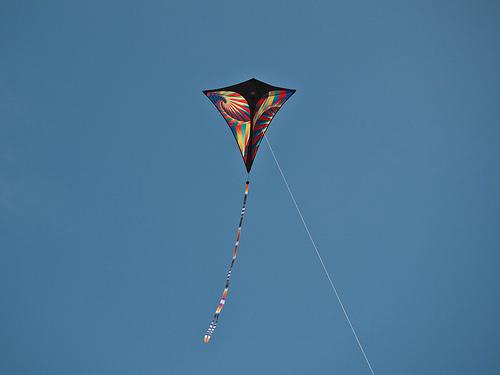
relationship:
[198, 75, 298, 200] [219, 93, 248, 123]
kite with print